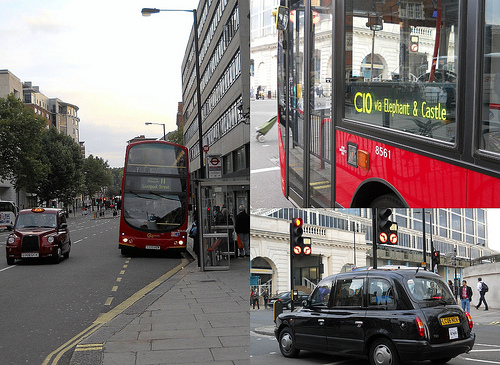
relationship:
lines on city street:
[100, 255, 131, 316] [0, 208, 196, 365]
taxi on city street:
[7, 204, 74, 264] [0, 207, 191, 361]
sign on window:
[342, 77, 451, 131] [334, 1, 461, 148]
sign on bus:
[342, 77, 451, 131] [274, 4, 498, 208]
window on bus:
[334, 1, 461, 148] [274, 4, 498, 208]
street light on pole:
[138, 5, 196, 18] [190, 9, 203, 268]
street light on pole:
[138, 5, 196, 18] [158, 124, 168, 143]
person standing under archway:
[261, 287, 271, 306] [246, 255, 276, 307]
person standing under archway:
[251, 284, 262, 310] [246, 255, 276, 307]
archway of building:
[246, 255, 276, 307] [248, 209, 367, 305]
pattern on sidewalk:
[106, 264, 252, 363] [99, 237, 250, 362]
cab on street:
[271, 267, 477, 363] [248, 304, 497, 363]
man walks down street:
[474, 276, 492, 314] [250, 297, 498, 359]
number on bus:
[371, 144, 396, 160] [274, 4, 498, 208]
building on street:
[177, 1, 251, 218] [1, 202, 191, 362]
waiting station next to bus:
[192, 174, 248, 272] [119, 137, 189, 258]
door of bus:
[285, 0, 336, 208] [274, 4, 498, 208]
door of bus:
[306, 0, 333, 208] [274, 4, 498, 208]